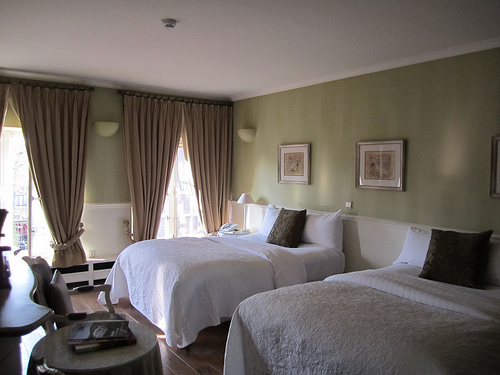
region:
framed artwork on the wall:
[355, 138, 406, 192]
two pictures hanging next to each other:
[276, 136, 407, 193]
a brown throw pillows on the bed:
[263, 207, 305, 247]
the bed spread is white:
[222, 270, 497, 373]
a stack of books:
[67, 319, 136, 351]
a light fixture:
[92, 121, 119, 137]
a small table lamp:
[237, 194, 252, 229]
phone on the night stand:
[218, 221, 237, 235]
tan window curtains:
[120, 88, 230, 238]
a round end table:
[31, 319, 161, 374]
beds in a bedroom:
[97, 172, 484, 374]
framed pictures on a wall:
[268, 128, 410, 198]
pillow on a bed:
[263, 202, 305, 252]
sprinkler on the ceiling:
[153, 11, 188, 39]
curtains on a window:
[116, 80, 241, 255]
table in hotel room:
[27, 306, 162, 371]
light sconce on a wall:
[86, 105, 116, 150]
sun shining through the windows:
[0, 121, 36, 236]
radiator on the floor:
[55, 260, 115, 290]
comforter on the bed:
[360, 265, 435, 356]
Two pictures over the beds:
[276, 138, 407, 194]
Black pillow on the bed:
[418, 225, 498, 284]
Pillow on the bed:
[265, 205, 313, 246]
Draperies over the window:
[122, 90, 237, 247]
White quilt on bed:
[98, 232, 305, 354]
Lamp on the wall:
[233, 118, 259, 145]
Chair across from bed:
[26, 252, 121, 329]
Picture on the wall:
[353, 136, 409, 197]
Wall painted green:
[233, 47, 498, 228]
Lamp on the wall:
[92, 115, 124, 141]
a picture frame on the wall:
[339, 134, 416, 212]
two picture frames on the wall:
[253, 129, 453, 233]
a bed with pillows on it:
[121, 159, 333, 342]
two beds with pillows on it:
[151, 160, 473, 370]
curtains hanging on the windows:
[5, 82, 259, 255]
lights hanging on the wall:
[85, 113, 285, 168]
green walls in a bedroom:
[272, 97, 467, 134]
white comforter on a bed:
[122, 213, 214, 324]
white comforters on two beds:
[170, 245, 353, 371]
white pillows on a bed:
[238, 192, 355, 264]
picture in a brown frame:
[348, 137, 413, 194]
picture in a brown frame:
[272, 139, 315, 188]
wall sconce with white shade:
[237, 122, 261, 144]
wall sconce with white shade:
[91, 119, 123, 137]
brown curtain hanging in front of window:
[182, 99, 241, 241]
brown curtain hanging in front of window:
[114, 93, 190, 246]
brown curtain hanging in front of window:
[0, 83, 101, 274]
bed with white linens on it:
[90, 197, 347, 348]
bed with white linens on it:
[217, 221, 498, 374]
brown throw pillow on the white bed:
[264, 204, 311, 249]